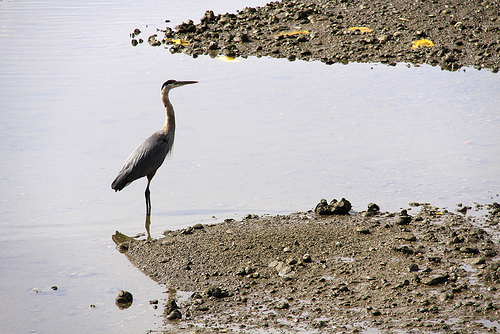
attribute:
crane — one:
[117, 69, 191, 232]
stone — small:
[277, 265, 293, 278]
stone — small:
[282, 244, 291, 254]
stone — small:
[300, 251, 310, 261]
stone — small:
[366, 244, 376, 253]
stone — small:
[406, 261, 421, 271]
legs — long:
[123, 167, 172, 257]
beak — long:
[174, 69, 201, 98]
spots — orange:
[169, 30, 440, 60]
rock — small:
[116, 278, 140, 311]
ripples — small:
[0, 23, 122, 108]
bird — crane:
[106, 75, 198, 243]